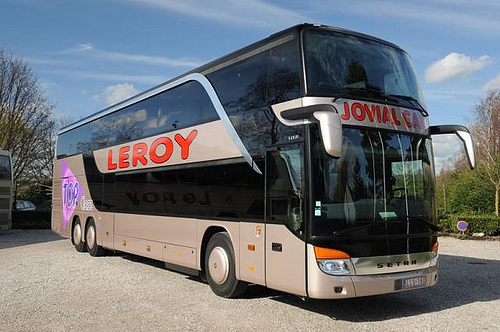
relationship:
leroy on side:
[107, 129, 199, 171] [50, 23, 310, 306]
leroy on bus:
[107, 129, 199, 171] [50, 22, 477, 303]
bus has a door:
[50, 22, 477, 303] [263, 142, 310, 300]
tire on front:
[202, 230, 249, 300] [299, 20, 444, 302]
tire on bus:
[202, 230, 249, 300] [50, 22, 477, 303]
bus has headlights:
[50, 22, 477, 303] [316, 258, 354, 277]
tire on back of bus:
[71, 214, 88, 253] [50, 22, 477, 303]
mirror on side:
[279, 102, 345, 161] [50, 23, 310, 306]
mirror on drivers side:
[426, 123, 478, 170] [375, 35, 443, 298]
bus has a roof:
[50, 22, 477, 303] [56, 22, 412, 136]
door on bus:
[263, 142, 310, 300] [50, 22, 477, 303]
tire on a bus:
[202, 230, 249, 300] [50, 22, 477, 303]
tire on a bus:
[71, 213, 86, 253] [50, 22, 477, 303]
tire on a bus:
[84, 216, 107, 257] [50, 22, 477, 303]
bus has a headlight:
[50, 22, 477, 303] [316, 258, 354, 277]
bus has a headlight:
[50, 22, 477, 303] [430, 250, 441, 265]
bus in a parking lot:
[50, 22, 477, 303] [2, 227, 500, 330]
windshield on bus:
[309, 122, 439, 237] [50, 22, 477, 303]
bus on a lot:
[50, 22, 477, 303] [2, 227, 500, 330]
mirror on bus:
[279, 102, 345, 161] [50, 22, 477, 303]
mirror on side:
[426, 123, 478, 170] [50, 23, 310, 306]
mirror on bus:
[426, 123, 478, 170] [50, 22, 477, 303]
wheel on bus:
[202, 230, 249, 300] [50, 22, 477, 303]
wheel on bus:
[84, 216, 107, 257] [50, 22, 477, 303]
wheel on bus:
[71, 213, 86, 253] [50, 22, 477, 303]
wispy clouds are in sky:
[21, 39, 178, 79] [2, 1, 497, 179]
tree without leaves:
[1, 46, 56, 214] [33, 112, 49, 133]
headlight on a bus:
[430, 250, 441, 265] [50, 22, 477, 303]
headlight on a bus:
[316, 258, 354, 277] [50, 22, 477, 303]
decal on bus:
[58, 159, 84, 236] [50, 22, 477, 303]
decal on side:
[58, 159, 84, 236] [50, 23, 310, 306]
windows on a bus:
[54, 25, 437, 257] [50, 22, 477, 303]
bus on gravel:
[50, 22, 477, 303] [2, 227, 499, 330]